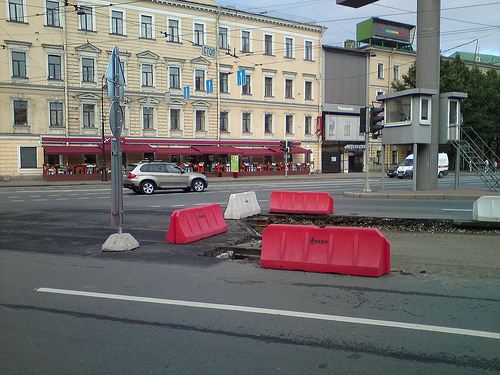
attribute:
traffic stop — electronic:
[354, 103, 391, 133]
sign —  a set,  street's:
[110, 139, 124, 228]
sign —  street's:
[108, 101, 123, 137]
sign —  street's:
[104, 45, 126, 102]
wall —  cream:
[156, 18, 328, 175]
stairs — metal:
[447, 123, 498, 189]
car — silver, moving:
[122, 161, 209, 196]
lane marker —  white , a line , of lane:
[37, 286, 498, 338]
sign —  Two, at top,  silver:
[96, 45, 133, 135]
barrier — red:
[259, 218, 394, 279]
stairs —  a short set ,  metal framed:
[450, 122, 499, 192]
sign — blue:
[218, 60, 256, 93]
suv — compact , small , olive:
[123, 161, 205, 196]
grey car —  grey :
[120, 158, 212, 195]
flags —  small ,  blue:
[176, 70, 253, 101]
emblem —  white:
[237, 71, 244, 83]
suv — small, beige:
[120, 162, 207, 194]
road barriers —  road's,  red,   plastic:
[153, 162, 420, 299]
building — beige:
[5, 2, 330, 189]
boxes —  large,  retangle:
[353, 82, 477, 166]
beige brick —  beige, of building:
[14, 21, 384, 169]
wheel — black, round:
[194, 178, 206, 196]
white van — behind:
[386, 150, 449, 175]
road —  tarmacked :
[0, 245, 495, 364]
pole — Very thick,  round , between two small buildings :
[411, 3, 449, 196]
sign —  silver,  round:
[107, 102, 126, 139]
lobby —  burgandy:
[47, 145, 304, 177]